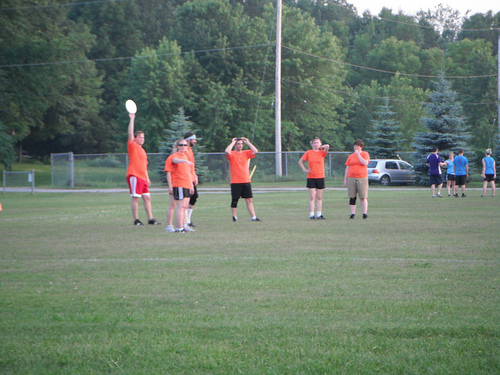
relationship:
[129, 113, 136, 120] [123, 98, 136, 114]
hand holding frisbee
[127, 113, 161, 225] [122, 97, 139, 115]
man holds frisbee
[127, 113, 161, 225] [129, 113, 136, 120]
man has hand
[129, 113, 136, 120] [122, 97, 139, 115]
hand has frisbee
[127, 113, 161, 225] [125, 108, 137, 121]
man has hand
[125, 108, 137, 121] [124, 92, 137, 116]
hand has frisbee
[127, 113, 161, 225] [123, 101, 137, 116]
man holds frisbee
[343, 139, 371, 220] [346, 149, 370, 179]
person wears shirt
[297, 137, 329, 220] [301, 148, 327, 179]
girl wears orange shirt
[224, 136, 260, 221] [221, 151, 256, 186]
man wears shirt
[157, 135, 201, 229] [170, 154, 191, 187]
player wears shirt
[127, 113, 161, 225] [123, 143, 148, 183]
man wears shirt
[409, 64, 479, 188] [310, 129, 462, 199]
blue spruce next to parking lot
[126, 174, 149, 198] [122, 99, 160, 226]
man wears short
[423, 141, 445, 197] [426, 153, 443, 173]
man wears purple shirt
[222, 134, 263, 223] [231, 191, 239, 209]
man wears brace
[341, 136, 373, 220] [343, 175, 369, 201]
person wears brown shorts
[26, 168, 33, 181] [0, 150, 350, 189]
sign on fence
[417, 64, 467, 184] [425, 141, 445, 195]
blue spruce behind person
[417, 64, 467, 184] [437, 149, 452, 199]
blue spruce behind person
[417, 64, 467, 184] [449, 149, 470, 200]
blue spruce behind person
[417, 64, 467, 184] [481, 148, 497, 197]
blue spruce behind boy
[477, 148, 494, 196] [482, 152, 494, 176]
boy wears blue shirt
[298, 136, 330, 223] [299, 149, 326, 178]
girl wearing orange shirt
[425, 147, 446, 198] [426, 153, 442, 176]
man has a purple shirt